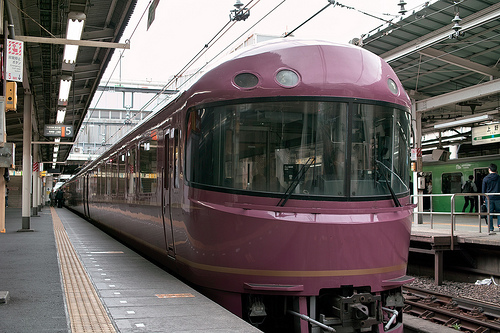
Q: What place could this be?
A: It is a train station.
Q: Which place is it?
A: It is a train station.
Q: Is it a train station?
A: Yes, it is a train station.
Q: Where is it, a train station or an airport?
A: It is a train station.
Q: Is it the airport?
A: No, it is the train station.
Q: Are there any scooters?
A: No, there are no scooters.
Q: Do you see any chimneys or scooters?
A: No, there are no scooters or chimneys.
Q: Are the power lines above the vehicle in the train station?
A: Yes, the power lines are above the train.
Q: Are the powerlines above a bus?
A: No, the powerlines are above the train.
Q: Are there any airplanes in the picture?
A: No, there are no airplanes.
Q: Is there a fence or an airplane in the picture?
A: No, there are no airplanes or fences.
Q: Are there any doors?
A: Yes, there is a door.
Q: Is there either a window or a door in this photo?
A: Yes, there is a door.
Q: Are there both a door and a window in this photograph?
A: Yes, there are both a door and a window.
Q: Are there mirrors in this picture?
A: No, there are no mirrors.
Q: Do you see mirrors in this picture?
A: No, there are no mirrors.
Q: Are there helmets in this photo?
A: No, there are no helmets.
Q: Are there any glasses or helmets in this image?
A: No, there are no helmets or glasses.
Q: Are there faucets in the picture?
A: No, there are no faucets.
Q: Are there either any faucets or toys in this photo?
A: No, there are no faucets or toys.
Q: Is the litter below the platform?
A: Yes, the litter is below the platform.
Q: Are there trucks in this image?
A: No, there are no trucks.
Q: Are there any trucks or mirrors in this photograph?
A: No, there are no trucks or mirrors.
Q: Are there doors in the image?
A: Yes, there is a door.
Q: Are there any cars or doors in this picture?
A: Yes, there is a door.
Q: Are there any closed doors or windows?
A: Yes, there is a closed door.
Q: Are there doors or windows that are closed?
A: Yes, the door is closed.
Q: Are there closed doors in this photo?
A: Yes, there is a closed door.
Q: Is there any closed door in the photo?
A: Yes, there is a closed door.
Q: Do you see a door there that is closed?
A: Yes, there is a door that is closed.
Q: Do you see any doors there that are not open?
A: Yes, there is an closed door.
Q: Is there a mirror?
A: No, there are no mirrors.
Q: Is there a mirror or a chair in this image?
A: No, there are no mirrors or chairs.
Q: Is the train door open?
A: No, the door is closed.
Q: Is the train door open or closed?
A: The door is closed.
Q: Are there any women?
A: No, there are no women.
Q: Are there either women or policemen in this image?
A: No, there are no women or policemen.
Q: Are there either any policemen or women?
A: No, there are no women or policemen.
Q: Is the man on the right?
A: Yes, the man is on the right of the image.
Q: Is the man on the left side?
A: No, the man is on the right of the image.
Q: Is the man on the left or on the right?
A: The man is on the right of the image.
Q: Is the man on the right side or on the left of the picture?
A: The man is on the right of the image.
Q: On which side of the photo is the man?
A: The man is on the right of the image.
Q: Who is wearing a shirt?
A: The man is wearing a shirt.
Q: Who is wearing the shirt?
A: The man is wearing a shirt.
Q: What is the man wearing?
A: The man is wearing a shirt.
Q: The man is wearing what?
A: The man is wearing a shirt.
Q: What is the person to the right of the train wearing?
A: The man is wearing a shirt.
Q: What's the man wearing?
A: The man is wearing a shirt.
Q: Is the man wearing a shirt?
A: Yes, the man is wearing a shirt.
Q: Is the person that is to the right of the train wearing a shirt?
A: Yes, the man is wearing a shirt.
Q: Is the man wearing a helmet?
A: No, the man is wearing a shirt.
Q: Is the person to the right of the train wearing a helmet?
A: No, the man is wearing a shirt.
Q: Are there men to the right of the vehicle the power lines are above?
A: Yes, there is a man to the right of the train.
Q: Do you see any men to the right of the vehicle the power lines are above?
A: Yes, there is a man to the right of the train.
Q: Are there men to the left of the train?
A: No, the man is to the right of the train.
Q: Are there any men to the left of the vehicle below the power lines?
A: No, the man is to the right of the train.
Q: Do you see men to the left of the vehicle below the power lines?
A: No, the man is to the right of the train.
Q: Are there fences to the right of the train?
A: No, there is a man to the right of the train.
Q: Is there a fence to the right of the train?
A: No, there is a man to the right of the train.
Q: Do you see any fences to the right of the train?
A: No, there is a man to the right of the train.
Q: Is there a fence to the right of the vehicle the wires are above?
A: No, there is a man to the right of the train.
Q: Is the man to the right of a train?
A: Yes, the man is to the right of a train.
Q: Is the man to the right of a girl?
A: No, the man is to the right of a train.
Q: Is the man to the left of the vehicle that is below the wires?
A: No, the man is to the right of the train.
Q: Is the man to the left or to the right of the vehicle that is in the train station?
A: The man is to the right of the train.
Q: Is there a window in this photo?
A: Yes, there are windows.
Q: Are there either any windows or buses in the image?
A: Yes, there are windows.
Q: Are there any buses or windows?
A: Yes, there are windows.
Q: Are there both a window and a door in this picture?
A: Yes, there are both a window and a door.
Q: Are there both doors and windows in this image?
A: Yes, there are both windows and a door.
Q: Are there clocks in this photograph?
A: No, there are no clocks.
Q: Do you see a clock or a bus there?
A: No, there are no clocks or buses.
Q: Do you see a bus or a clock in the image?
A: No, there are no clocks or buses.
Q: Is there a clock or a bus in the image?
A: No, there are no clocks or buses.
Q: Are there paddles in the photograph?
A: No, there are no paddles.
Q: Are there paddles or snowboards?
A: No, there are no paddles or snowboards.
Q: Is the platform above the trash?
A: Yes, the platform is above the trash.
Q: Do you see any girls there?
A: No, there are no girls.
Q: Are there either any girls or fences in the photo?
A: No, there are no girls or fences.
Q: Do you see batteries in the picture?
A: No, there are no batteries.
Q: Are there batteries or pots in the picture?
A: No, there are no batteries or pots.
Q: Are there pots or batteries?
A: No, there are no batteries or pots.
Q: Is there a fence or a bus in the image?
A: No, there are no fences or buses.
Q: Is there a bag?
A: No, there are no bags.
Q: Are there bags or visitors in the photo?
A: No, there are no bags or visitors.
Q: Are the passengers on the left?
A: Yes, the passengers are on the left of the image.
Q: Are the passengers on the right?
A: No, the passengers are on the left of the image.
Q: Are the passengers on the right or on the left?
A: The passengers are on the left of the image.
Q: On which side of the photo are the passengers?
A: The passengers are on the left of the image.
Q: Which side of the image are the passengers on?
A: The passengers are on the left of the image.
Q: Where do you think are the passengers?
A: The passengers are at the train station.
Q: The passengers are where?
A: The passengers are at the train station.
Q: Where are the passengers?
A: The passengers are at the train station.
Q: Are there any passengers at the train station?
A: Yes, there are passengers at the train station.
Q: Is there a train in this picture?
A: Yes, there is a train.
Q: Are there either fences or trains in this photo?
A: Yes, there is a train.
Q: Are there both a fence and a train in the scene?
A: No, there is a train but no fences.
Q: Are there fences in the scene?
A: No, there are no fences.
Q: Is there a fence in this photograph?
A: No, there are no fences.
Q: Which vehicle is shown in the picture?
A: The vehicle is a train.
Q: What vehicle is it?
A: The vehicle is a train.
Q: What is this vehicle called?
A: That is a train.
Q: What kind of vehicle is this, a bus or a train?
A: That is a train.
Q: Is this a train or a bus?
A: This is a train.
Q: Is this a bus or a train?
A: This is a train.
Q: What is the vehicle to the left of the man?
A: The vehicle is a train.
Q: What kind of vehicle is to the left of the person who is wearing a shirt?
A: The vehicle is a train.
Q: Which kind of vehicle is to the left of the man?
A: The vehicle is a train.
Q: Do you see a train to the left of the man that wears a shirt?
A: Yes, there is a train to the left of the man.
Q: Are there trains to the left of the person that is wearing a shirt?
A: Yes, there is a train to the left of the man.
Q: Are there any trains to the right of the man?
A: No, the train is to the left of the man.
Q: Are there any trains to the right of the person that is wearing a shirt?
A: No, the train is to the left of the man.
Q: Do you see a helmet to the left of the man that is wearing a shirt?
A: No, there is a train to the left of the man.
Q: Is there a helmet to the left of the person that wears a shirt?
A: No, there is a train to the left of the man.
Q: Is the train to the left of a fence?
A: No, the train is to the left of the man.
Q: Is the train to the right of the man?
A: No, the train is to the left of the man.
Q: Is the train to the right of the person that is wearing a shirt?
A: No, the train is to the left of the man.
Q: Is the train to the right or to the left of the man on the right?
A: The train is to the left of the man.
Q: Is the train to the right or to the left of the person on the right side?
A: The train is to the left of the man.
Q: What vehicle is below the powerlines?
A: The vehicle is a train.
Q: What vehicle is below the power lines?
A: The vehicle is a train.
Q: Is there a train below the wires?
A: Yes, there is a train below the wires.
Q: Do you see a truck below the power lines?
A: No, there is a train below the power lines.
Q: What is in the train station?
A: The train is in the train station.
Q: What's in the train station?
A: The train is in the train station.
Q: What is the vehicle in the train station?
A: The vehicle is a train.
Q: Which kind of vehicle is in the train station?
A: The vehicle is a train.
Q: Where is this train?
A: The train is in the train station.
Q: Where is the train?
A: The train is in the train station.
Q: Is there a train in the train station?
A: Yes, there is a train in the train station.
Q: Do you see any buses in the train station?
A: No, there is a train in the train station.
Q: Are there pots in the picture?
A: No, there are no pots.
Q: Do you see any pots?
A: No, there are no pots.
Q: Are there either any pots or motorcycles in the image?
A: No, there are no pots or motorcycles.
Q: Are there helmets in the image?
A: No, there are no helmets.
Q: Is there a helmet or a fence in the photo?
A: No, there are no helmets or fences.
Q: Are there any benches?
A: No, there are no benches.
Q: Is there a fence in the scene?
A: No, there are no fences.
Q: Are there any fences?
A: No, there are no fences.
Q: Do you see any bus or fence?
A: No, there are no fences or buses.